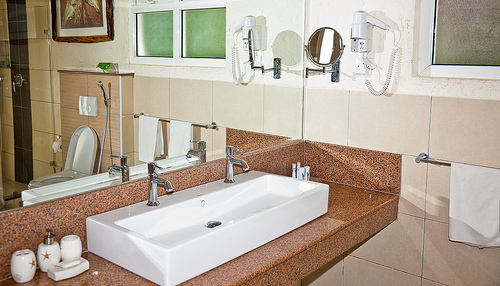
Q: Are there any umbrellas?
A: No, there are no umbrellas.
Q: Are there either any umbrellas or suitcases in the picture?
A: No, there are no umbrellas or suitcases.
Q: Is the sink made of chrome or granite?
A: The sink is made of chrome.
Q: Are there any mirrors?
A: Yes, there is a mirror.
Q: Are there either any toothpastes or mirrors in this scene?
A: Yes, there is a mirror.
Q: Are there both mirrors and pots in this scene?
A: No, there is a mirror but no pots.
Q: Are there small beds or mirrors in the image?
A: Yes, there is a small mirror.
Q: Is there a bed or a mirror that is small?
A: Yes, the mirror is small.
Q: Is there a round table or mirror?
A: Yes, there is a round mirror.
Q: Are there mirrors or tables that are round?
A: Yes, the mirror is round.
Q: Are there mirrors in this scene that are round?
A: Yes, there is a round mirror.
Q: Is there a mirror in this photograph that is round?
A: Yes, there is a mirror that is round.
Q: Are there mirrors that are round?
A: Yes, there is a mirror that is round.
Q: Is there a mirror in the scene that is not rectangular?
A: Yes, there is a round mirror.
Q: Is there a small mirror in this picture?
A: Yes, there is a small mirror.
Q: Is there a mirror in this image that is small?
A: Yes, there is a mirror that is small.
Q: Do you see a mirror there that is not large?
A: Yes, there is a small mirror.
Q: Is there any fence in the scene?
A: No, there are no fences.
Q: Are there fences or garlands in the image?
A: No, there are no fences or garlands.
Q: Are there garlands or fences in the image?
A: No, there are no fences or garlands.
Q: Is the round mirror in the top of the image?
A: Yes, the mirror is in the top of the image.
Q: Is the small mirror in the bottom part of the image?
A: No, the mirror is in the top of the image.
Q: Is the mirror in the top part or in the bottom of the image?
A: The mirror is in the top of the image.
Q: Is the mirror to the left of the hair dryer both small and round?
A: Yes, the mirror is small and round.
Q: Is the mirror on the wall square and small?
A: No, the mirror is small but round.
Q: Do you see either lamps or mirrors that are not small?
A: No, there is a mirror but it is small.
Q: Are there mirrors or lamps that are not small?
A: No, there is a mirror but it is small.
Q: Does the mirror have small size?
A: Yes, the mirror is small.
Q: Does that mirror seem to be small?
A: Yes, the mirror is small.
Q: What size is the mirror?
A: The mirror is small.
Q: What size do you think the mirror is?
A: The mirror is small.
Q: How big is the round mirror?
A: The mirror is small.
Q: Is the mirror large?
A: No, the mirror is small.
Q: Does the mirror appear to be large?
A: No, the mirror is small.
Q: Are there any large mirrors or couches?
A: No, there is a mirror but it is small.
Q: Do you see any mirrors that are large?
A: No, there is a mirror but it is small.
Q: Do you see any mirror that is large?
A: No, there is a mirror but it is small.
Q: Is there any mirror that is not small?
A: No, there is a mirror but it is small.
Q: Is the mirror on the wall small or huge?
A: The mirror is small.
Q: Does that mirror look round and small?
A: Yes, the mirror is round and small.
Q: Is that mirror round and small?
A: Yes, the mirror is round and small.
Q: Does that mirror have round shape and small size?
A: Yes, the mirror is round and small.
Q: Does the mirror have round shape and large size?
A: No, the mirror is round but small.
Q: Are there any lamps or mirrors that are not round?
A: No, there is a mirror but it is round.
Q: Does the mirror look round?
A: Yes, the mirror is round.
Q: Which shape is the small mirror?
A: The mirror is round.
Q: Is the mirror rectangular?
A: No, the mirror is round.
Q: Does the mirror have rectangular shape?
A: No, the mirror is round.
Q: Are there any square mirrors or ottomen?
A: No, there is a mirror but it is round.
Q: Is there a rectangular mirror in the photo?
A: No, there is a mirror but it is round.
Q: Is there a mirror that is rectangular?
A: No, there is a mirror but it is round.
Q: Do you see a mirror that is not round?
A: No, there is a mirror but it is round.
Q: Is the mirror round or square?
A: The mirror is round.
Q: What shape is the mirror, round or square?
A: The mirror is round.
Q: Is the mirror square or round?
A: The mirror is round.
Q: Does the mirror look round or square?
A: The mirror is round.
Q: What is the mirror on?
A: The mirror is on the wall.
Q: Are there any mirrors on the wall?
A: Yes, there is a mirror on the wall.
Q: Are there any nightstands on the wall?
A: No, there is a mirror on the wall.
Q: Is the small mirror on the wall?
A: Yes, the mirror is on the wall.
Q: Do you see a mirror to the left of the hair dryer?
A: Yes, there is a mirror to the left of the hair dryer.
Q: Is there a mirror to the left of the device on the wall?
A: Yes, there is a mirror to the left of the hair dryer.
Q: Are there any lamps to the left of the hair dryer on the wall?
A: No, there is a mirror to the left of the hair dryer.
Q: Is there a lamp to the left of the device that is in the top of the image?
A: No, there is a mirror to the left of the hair dryer.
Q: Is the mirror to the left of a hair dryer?
A: Yes, the mirror is to the left of a hair dryer.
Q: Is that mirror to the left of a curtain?
A: No, the mirror is to the left of a hair dryer.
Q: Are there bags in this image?
A: No, there are no bags.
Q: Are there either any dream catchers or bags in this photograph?
A: No, there are no bags or dream catchers.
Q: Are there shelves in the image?
A: No, there are no shelves.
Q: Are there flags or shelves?
A: No, there are no shelves or flags.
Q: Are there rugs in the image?
A: No, there are no rugs.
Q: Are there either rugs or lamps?
A: No, there are no rugs or lamps.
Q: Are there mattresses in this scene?
A: No, there are no mattresses.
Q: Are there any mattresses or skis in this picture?
A: No, there are no mattresses or skis.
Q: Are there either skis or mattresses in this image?
A: No, there are no mattresses or skis.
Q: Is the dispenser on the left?
A: Yes, the dispenser is on the left of the image.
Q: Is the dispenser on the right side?
A: No, the dispenser is on the left of the image.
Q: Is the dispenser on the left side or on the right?
A: The dispenser is on the left of the image.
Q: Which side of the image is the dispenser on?
A: The dispenser is on the left of the image.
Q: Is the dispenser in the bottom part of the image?
A: Yes, the dispenser is in the bottom of the image.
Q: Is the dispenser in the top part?
A: No, the dispenser is in the bottom of the image.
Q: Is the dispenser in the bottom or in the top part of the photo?
A: The dispenser is in the bottom of the image.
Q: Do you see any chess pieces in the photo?
A: No, there are no chess pieces.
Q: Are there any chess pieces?
A: No, there are no chess pieces.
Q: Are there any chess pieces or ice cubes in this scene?
A: No, there are no chess pieces or ice cubes.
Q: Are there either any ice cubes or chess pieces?
A: No, there are no chess pieces or ice cubes.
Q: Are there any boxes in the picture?
A: No, there are no boxes.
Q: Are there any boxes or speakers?
A: No, there are no boxes or speakers.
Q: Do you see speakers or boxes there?
A: No, there are no boxes or speakers.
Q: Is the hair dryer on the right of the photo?
A: Yes, the hair dryer is on the right of the image.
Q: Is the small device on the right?
A: Yes, the hair dryer is on the right of the image.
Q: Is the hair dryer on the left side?
A: No, the hair dryer is on the right of the image.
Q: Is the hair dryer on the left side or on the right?
A: The hair dryer is on the right of the image.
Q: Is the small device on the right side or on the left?
A: The hair dryer is on the right of the image.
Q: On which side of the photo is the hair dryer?
A: The hair dryer is on the right of the image.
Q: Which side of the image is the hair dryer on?
A: The hair dryer is on the right of the image.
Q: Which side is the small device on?
A: The hair dryer is on the right of the image.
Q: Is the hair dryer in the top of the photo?
A: Yes, the hair dryer is in the top of the image.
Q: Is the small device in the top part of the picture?
A: Yes, the hair dryer is in the top of the image.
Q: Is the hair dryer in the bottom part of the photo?
A: No, the hair dryer is in the top of the image.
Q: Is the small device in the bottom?
A: No, the hair dryer is in the top of the image.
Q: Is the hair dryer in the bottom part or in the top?
A: The hair dryer is in the top of the image.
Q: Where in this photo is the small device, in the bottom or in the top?
A: The hair dryer is in the top of the image.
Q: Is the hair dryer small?
A: Yes, the hair dryer is small.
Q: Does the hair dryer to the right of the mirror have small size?
A: Yes, the hair dryer is small.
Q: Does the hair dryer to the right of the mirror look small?
A: Yes, the hair dryer is small.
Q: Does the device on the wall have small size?
A: Yes, the hair dryer is small.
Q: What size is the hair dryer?
A: The hair dryer is small.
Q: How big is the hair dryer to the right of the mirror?
A: The hair dryer is small.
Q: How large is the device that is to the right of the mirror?
A: The hair dryer is small.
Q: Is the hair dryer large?
A: No, the hair dryer is small.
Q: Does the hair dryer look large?
A: No, the hair dryer is small.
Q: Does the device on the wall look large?
A: No, the hair dryer is small.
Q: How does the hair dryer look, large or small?
A: The hair dryer is small.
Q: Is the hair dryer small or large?
A: The hair dryer is small.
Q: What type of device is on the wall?
A: The device is a hair dryer.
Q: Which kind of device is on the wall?
A: The device is a hair dryer.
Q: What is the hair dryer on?
A: The hair dryer is on the wall.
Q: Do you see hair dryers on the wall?
A: Yes, there is a hair dryer on the wall.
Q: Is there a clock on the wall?
A: No, there is a hair dryer on the wall.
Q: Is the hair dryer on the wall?
A: Yes, the hair dryer is on the wall.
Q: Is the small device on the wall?
A: Yes, the hair dryer is on the wall.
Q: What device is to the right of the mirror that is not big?
A: The device is a hair dryer.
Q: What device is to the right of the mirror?
A: The device is a hair dryer.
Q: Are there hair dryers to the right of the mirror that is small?
A: Yes, there is a hair dryer to the right of the mirror.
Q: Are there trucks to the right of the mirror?
A: No, there is a hair dryer to the right of the mirror.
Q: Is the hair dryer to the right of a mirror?
A: Yes, the hair dryer is to the right of a mirror.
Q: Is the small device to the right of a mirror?
A: Yes, the hair dryer is to the right of a mirror.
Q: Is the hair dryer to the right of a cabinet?
A: No, the hair dryer is to the right of a mirror.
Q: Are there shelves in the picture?
A: No, there are no shelves.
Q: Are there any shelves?
A: No, there are no shelves.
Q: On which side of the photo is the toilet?
A: The toilet is on the left of the image.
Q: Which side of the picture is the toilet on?
A: The toilet is on the left of the image.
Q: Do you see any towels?
A: Yes, there is a towel.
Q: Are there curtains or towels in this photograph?
A: Yes, there is a towel.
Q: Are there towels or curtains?
A: Yes, there is a towel.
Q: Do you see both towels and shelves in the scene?
A: No, there is a towel but no shelves.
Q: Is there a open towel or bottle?
A: Yes, there is an open towel.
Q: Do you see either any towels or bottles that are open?
A: Yes, the towel is open.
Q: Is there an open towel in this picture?
A: Yes, there is an open towel.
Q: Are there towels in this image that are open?
A: Yes, there is a towel that is open.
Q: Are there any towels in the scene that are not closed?
A: Yes, there is a open towel.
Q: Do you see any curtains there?
A: No, there are no curtains.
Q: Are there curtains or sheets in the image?
A: No, there are no curtains or sheets.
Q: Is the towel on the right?
A: Yes, the towel is on the right of the image.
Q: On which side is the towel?
A: The towel is on the right of the image.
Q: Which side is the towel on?
A: The towel is on the right of the image.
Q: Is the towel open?
A: Yes, the towel is open.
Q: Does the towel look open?
A: Yes, the towel is open.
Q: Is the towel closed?
A: No, the towel is open.